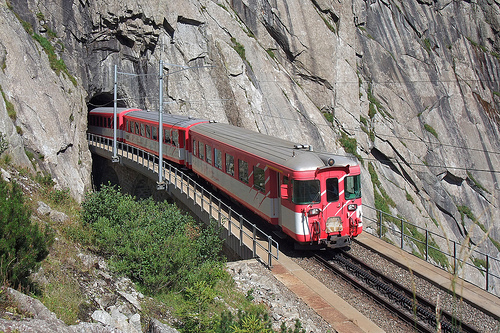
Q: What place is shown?
A: It is a railroad.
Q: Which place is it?
A: It is a railroad.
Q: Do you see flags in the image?
A: No, there are no flags.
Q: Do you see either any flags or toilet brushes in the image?
A: No, there are no flags or toilet brushes.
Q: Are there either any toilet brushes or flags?
A: No, there are no flags or toilet brushes.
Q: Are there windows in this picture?
A: Yes, there are windows.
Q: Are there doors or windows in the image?
A: Yes, there are windows.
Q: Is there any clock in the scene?
A: No, there are no clocks.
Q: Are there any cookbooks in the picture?
A: No, there are no cookbooks.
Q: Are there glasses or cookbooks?
A: No, there are no cookbooks or glasses.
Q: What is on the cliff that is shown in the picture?
A: The plants are on the cliff.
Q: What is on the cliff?
A: The plants are on the cliff.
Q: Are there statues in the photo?
A: No, there are no statues.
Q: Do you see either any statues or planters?
A: No, there are no statues or planters.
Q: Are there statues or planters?
A: No, there are no statues or planters.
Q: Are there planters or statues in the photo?
A: No, there are no statues or planters.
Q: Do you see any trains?
A: Yes, there is a train.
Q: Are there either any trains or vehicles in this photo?
A: Yes, there is a train.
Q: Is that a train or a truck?
A: That is a train.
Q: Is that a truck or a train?
A: That is a train.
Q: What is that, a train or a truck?
A: That is a train.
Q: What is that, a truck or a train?
A: That is a train.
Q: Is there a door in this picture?
A: Yes, there is a door.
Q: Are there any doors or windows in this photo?
A: Yes, there is a door.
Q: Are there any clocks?
A: No, there are no clocks.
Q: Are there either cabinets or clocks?
A: No, there are no clocks or cabinets.